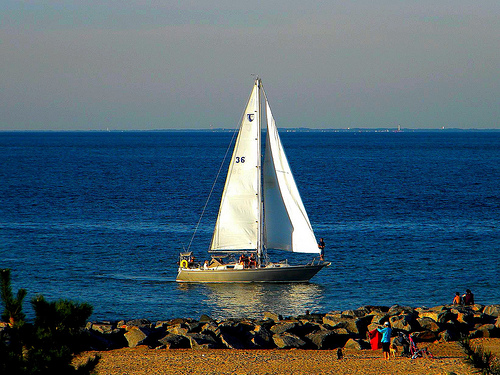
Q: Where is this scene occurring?
A: An ocean shore.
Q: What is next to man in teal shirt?
A: A dog.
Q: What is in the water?
A: A sailboat.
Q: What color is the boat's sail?
A: White.